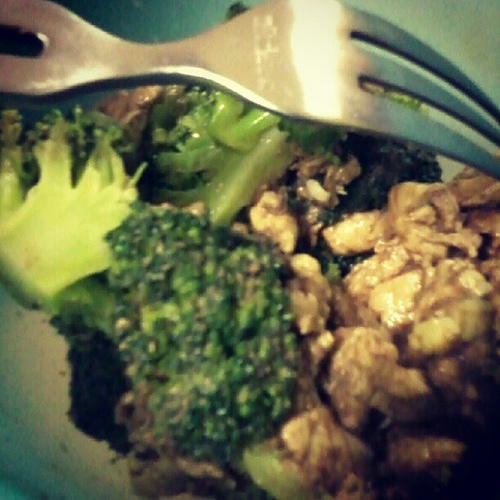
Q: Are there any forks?
A: Yes, there is a fork.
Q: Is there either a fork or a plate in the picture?
A: Yes, there is a fork.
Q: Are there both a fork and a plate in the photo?
A: Yes, there are both a fork and a plate.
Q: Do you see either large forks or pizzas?
A: Yes, there is a large fork.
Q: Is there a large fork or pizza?
A: Yes, there is a large fork.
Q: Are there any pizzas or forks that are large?
A: Yes, the fork is large.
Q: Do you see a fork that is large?
A: Yes, there is a large fork.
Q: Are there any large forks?
A: Yes, there is a large fork.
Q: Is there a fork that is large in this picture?
A: Yes, there is a large fork.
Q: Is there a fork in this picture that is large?
A: Yes, there is a fork that is large.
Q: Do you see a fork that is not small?
A: Yes, there is a large fork.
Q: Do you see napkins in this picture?
A: No, there are no napkins.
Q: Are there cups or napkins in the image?
A: No, there are no napkins or cups.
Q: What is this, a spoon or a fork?
A: This is a fork.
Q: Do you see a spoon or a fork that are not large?
A: No, there is a fork but it is large.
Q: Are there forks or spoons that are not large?
A: No, there is a fork but it is large.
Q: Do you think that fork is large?
A: Yes, the fork is large.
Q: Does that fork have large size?
A: Yes, the fork is large.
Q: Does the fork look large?
A: Yes, the fork is large.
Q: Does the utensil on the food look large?
A: Yes, the fork is large.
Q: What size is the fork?
A: The fork is large.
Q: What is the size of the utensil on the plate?
A: The fork is large.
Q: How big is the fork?
A: The fork is large.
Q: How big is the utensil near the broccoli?
A: The fork is large.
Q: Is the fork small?
A: No, the fork is large.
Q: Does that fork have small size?
A: No, the fork is large.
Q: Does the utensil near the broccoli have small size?
A: No, the fork is large.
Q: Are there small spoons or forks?
A: No, there is a fork but it is large.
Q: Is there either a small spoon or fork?
A: No, there is a fork but it is large.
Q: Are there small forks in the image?
A: No, there is a fork but it is large.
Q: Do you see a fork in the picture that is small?
A: No, there is a fork but it is large.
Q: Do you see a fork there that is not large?
A: No, there is a fork but it is large.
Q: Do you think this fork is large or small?
A: The fork is large.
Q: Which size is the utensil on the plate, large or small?
A: The fork is large.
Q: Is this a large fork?
A: Yes, this is a large fork.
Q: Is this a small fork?
A: No, this is a large fork.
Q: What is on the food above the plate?
A: The fork is on the food.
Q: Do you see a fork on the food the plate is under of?
A: Yes, there is a fork on the food.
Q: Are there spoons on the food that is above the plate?
A: No, there is a fork on the food.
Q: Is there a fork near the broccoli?
A: Yes, there is a fork near the broccoli.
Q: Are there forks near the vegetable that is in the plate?
A: Yes, there is a fork near the broccoli.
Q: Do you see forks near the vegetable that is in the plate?
A: Yes, there is a fork near the broccoli.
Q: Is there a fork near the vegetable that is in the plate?
A: Yes, there is a fork near the broccoli.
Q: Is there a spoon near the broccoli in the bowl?
A: No, there is a fork near the broccoli.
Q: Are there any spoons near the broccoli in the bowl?
A: No, there is a fork near the broccoli.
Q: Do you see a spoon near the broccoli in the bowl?
A: No, there is a fork near the broccoli.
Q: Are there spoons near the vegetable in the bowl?
A: No, there is a fork near the broccoli.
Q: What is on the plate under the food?
A: The fork is on the plate.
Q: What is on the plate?
A: The fork is on the plate.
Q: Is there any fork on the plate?
A: Yes, there is a fork on the plate.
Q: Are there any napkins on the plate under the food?
A: No, there is a fork on the plate.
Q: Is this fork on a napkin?
A: No, the fork is on a plate.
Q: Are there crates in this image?
A: No, there are no crates.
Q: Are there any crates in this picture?
A: No, there are no crates.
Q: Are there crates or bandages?
A: No, there are no crates or bandages.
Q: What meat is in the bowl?
A: The meat is chicken.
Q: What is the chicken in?
A: The chicken is in the bowl.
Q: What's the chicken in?
A: The chicken is in the bowl.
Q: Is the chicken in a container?
A: No, the chicken is in the bowl.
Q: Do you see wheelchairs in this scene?
A: No, there are no wheelchairs.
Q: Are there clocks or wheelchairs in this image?
A: No, there are no wheelchairs or clocks.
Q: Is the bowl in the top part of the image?
A: Yes, the bowl is in the top of the image.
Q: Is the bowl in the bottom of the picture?
A: No, the bowl is in the top of the image.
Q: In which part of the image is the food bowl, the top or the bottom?
A: The bowl is in the top of the image.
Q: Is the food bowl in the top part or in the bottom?
A: The bowl is in the top of the image.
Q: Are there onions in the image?
A: Yes, there is an onion.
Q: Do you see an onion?
A: Yes, there is an onion.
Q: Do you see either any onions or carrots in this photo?
A: Yes, there is an onion.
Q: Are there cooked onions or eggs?
A: Yes, there is a cooked onion.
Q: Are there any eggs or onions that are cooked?
A: Yes, the onion is cooked.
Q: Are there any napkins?
A: No, there are no napkins.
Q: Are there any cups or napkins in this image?
A: No, there are no napkins or cups.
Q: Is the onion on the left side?
A: Yes, the onion is on the left of the image.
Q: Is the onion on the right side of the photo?
A: No, the onion is on the left of the image.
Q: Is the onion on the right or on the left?
A: The onion is on the left of the image.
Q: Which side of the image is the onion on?
A: The onion is on the left of the image.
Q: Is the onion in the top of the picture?
A: Yes, the onion is in the top of the image.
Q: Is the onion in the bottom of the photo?
A: No, the onion is in the top of the image.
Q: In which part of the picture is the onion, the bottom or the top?
A: The onion is in the top of the image.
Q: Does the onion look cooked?
A: Yes, the onion is cooked.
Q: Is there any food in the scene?
A: Yes, there is food.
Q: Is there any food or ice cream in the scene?
A: Yes, there is food.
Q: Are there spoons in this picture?
A: No, there are no spoons.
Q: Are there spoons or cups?
A: No, there are no spoons or cups.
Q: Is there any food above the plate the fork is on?
A: Yes, there is food above the plate.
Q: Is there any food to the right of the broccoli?
A: Yes, there is food to the right of the broccoli.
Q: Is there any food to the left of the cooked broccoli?
A: No, the food is to the right of the broccoli.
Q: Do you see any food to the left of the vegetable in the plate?
A: No, the food is to the right of the broccoli.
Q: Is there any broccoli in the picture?
A: Yes, there is broccoli.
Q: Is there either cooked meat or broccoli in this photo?
A: Yes, there is cooked broccoli.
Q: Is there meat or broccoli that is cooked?
A: Yes, the broccoli is cooked.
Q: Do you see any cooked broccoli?
A: Yes, there is cooked broccoli.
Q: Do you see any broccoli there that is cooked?
A: Yes, there is broccoli that is cooked.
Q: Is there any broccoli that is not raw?
A: Yes, there is cooked broccoli.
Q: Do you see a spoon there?
A: No, there are no spoons.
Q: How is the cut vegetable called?
A: The vegetable is broccoli.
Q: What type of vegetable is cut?
A: The vegetable is broccoli.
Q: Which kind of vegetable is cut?
A: The vegetable is broccoli.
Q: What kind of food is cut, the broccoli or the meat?
A: The broccoli is cut.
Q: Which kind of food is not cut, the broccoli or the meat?
A: The meat is not cut.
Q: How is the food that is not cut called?
A: The food is meat.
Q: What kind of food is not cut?
A: The food is meat.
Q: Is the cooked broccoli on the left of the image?
A: Yes, the broccoli is on the left of the image.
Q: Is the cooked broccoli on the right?
A: No, the broccoli is on the left of the image.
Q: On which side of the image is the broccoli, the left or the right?
A: The broccoli is on the left of the image.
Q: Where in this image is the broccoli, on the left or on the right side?
A: The broccoli is on the left of the image.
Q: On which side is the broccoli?
A: The broccoli is on the left of the image.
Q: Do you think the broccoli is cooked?
A: Yes, the broccoli is cooked.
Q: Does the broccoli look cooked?
A: Yes, the broccoli is cooked.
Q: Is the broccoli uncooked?
A: No, the broccoli is cooked.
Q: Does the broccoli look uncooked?
A: No, the broccoli is cooked.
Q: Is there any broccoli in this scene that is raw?
A: No, there is broccoli but it is cooked.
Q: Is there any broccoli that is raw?
A: No, there is broccoli but it is cooked.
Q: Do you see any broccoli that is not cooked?
A: No, there is broccoli but it is cooked.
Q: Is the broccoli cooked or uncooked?
A: The broccoli is cooked.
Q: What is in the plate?
A: The broccoli is in the plate.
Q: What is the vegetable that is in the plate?
A: The vegetable is broccoli.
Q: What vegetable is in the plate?
A: The vegetable is broccoli.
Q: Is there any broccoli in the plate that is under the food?
A: Yes, there is broccoli in the plate.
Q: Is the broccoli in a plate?
A: Yes, the broccoli is in a plate.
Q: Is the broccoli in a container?
A: No, the broccoli is in a plate.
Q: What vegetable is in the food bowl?
A: The vegetable is broccoli.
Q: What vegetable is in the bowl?
A: The vegetable is broccoli.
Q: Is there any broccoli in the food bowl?
A: Yes, there is broccoli in the bowl.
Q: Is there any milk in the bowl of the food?
A: No, there is broccoli in the bowl.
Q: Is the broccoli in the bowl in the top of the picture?
A: Yes, the broccoli is in the bowl.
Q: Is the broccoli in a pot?
A: No, the broccoli is in the bowl.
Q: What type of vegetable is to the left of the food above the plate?
A: The vegetable is broccoli.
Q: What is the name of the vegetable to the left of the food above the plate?
A: The vegetable is broccoli.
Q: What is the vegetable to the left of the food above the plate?
A: The vegetable is broccoli.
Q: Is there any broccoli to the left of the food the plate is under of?
A: Yes, there is broccoli to the left of the food.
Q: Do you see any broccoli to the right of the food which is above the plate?
A: No, the broccoli is to the left of the food.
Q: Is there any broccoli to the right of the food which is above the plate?
A: No, the broccoli is to the left of the food.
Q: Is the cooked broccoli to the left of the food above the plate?
A: Yes, the broccoli is to the left of the food.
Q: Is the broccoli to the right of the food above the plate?
A: No, the broccoli is to the left of the food.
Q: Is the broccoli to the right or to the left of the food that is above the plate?
A: The broccoli is to the left of the food.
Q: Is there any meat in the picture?
A: Yes, there is meat.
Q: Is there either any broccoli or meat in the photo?
A: Yes, there is meat.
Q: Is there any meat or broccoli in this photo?
A: Yes, there is meat.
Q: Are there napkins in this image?
A: No, there are no napkins.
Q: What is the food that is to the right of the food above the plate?
A: The food is meat.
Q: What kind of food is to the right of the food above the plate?
A: The food is meat.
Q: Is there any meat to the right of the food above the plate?
A: Yes, there is meat to the right of the food.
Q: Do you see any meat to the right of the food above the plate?
A: Yes, there is meat to the right of the food.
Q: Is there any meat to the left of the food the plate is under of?
A: No, the meat is to the right of the food.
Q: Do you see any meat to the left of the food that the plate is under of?
A: No, the meat is to the right of the food.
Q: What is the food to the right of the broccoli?
A: The food is meat.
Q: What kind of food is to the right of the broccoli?
A: The food is meat.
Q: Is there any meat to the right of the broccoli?
A: Yes, there is meat to the right of the broccoli.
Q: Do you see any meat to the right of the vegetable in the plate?
A: Yes, there is meat to the right of the broccoli.